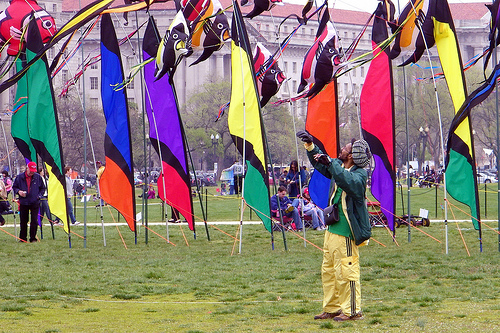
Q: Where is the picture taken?
A: The park.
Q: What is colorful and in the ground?
A: Flags.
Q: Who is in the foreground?
A: A black man.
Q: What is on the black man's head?
A: A hat.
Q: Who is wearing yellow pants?
A: The black man.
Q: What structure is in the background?
A: White building.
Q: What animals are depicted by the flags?
A: Fish.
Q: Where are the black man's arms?
A: In the air.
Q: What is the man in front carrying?
A: A bag.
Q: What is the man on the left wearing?
A: A red hat.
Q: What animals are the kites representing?
A: Fish.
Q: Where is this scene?
A: In a park.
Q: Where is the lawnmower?
A: Behind the flags.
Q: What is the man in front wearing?
A: Yellow pants.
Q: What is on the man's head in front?
A: A hat.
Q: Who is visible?
A: A man.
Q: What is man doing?
A: Standing.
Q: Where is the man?
A: In grass.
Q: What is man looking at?
A: Flags.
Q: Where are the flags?
A: Behind man.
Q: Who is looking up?
A: A man.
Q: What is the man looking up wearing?
A: Jacket.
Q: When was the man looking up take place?
A: Daytime.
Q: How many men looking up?
A: One.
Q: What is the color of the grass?
A: Green.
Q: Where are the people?
A: At the park.